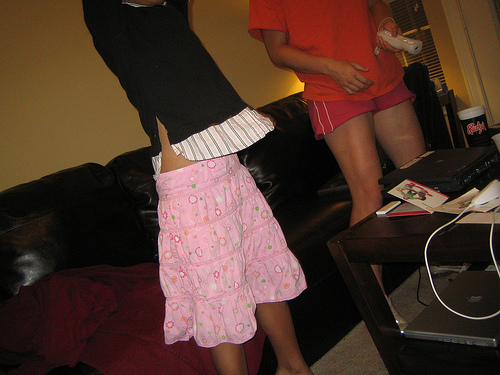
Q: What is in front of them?
A: A table.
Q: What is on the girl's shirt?
A: Stripes.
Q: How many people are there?
A: Two.